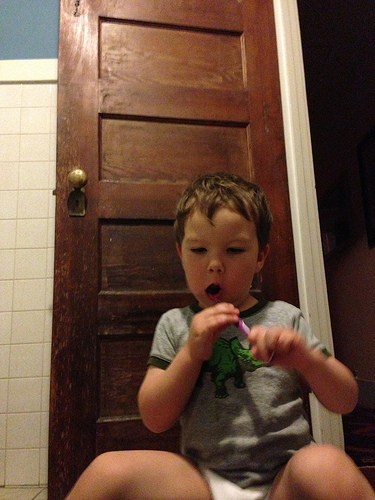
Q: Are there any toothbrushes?
A: Yes, there is a toothbrush.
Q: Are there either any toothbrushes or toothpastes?
A: Yes, there is a toothbrush.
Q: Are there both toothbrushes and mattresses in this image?
A: No, there is a toothbrush but no mattresses.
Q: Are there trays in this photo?
A: No, there are no trays.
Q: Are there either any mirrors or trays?
A: No, there are no trays or mirrors.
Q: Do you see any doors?
A: Yes, there is a door.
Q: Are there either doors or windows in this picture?
A: Yes, there is a door.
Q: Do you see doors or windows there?
A: Yes, there is a door.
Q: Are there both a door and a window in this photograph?
A: No, there is a door but no windows.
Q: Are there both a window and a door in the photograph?
A: No, there is a door but no windows.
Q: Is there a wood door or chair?
A: Yes, there is a wood door.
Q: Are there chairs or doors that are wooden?
A: Yes, the door is wooden.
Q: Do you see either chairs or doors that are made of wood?
A: Yes, the door is made of wood.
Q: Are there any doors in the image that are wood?
A: Yes, there is a wood door.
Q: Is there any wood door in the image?
A: Yes, there is a wood door.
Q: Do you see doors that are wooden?
A: Yes, there is a wood door.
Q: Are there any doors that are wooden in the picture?
A: Yes, there is a wood door.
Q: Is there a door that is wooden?
A: Yes, there is a door that is wooden.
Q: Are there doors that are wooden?
A: Yes, there is a door that is wooden.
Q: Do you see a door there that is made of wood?
A: Yes, there is a door that is made of wood.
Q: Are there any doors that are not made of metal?
A: Yes, there is a door that is made of wood.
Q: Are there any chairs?
A: No, there are no chairs.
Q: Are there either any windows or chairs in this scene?
A: No, there are no chairs or windows.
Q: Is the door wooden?
A: Yes, the door is wooden.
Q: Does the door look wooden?
A: Yes, the door is wooden.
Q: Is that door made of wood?
A: Yes, the door is made of wood.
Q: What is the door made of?
A: The door is made of wood.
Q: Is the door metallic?
A: No, the door is wooden.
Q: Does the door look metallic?
A: No, the door is wooden.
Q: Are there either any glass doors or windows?
A: No, there is a door but it is wooden.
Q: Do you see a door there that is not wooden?
A: No, there is a door but it is wooden.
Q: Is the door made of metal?
A: No, the door is made of wood.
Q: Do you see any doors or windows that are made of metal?
A: No, there is a door but it is made of wood.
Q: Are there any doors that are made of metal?
A: No, there is a door but it is made of wood.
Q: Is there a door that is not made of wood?
A: No, there is a door but it is made of wood.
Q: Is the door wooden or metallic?
A: The door is wooden.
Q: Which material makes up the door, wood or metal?
A: The door is made of wood.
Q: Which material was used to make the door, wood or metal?
A: The door is made of wood.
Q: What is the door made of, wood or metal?
A: The door is made of wood.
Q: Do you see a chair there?
A: No, there are no chairs.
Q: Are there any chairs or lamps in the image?
A: No, there are no chairs or lamps.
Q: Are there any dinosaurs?
A: Yes, there is a dinosaur.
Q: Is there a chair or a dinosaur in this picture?
A: Yes, there is a dinosaur.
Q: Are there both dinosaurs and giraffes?
A: No, there is a dinosaur but no giraffes.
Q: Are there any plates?
A: No, there are no plates.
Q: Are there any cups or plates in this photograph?
A: No, there are no plates or cups.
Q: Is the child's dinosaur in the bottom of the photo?
A: Yes, the dinosaur is in the bottom of the image.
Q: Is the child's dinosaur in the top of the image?
A: No, the dinosaur is in the bottom of the image.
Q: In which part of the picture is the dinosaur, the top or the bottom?
A: The dinosaur is in the bottom of the image.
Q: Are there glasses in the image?
A: No, there are no glasses.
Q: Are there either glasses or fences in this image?
A: No, there are no glasses or fences.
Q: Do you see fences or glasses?
A: No, there are no glasses or fences.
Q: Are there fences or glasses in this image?
A: No, there are no glasses or fences.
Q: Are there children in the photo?
A: Yes, there is a child.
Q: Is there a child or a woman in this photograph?
A: Yes, there is a child.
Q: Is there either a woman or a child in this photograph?
A: Yes, there is a child.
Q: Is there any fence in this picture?
A: No, there are no fences.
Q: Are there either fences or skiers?
A: No, there are no fences or skiers.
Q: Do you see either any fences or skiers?
A: No, there are no fences or skiers.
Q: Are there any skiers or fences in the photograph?
A: No, there are no fences or skiers.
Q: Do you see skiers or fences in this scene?
A: No, there are no fences or skiers.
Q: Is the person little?
A: Yes, the child is little.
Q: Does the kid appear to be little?
A: Yes, the kid is little.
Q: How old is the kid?
A: The kid is little.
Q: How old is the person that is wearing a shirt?
A: The kid is little.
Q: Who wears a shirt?
A: The kid wears a shirt.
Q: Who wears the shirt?
A: The kid wears a shirt.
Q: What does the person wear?
A: The kid wears a shirt.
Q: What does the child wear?
A: The kid wears a shirt.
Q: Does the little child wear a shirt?
A: Yes, the child wears a shirt.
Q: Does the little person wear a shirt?
A: Yes, the child wears a shirt.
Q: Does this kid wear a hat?
A: No, the kid wears a shirt.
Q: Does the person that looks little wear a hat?
A: No, the kid wears a shirt.